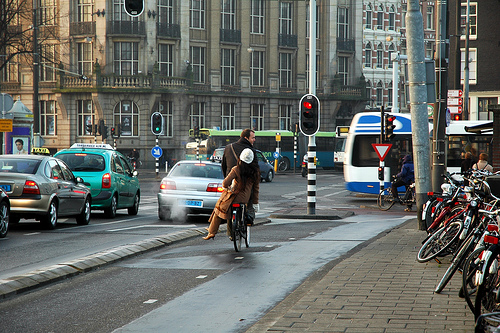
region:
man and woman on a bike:
[204, 127, 278, 253]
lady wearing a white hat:
[210, 148, 264, 236]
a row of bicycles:
[425, 161, 498, 331]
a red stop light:
[292, 92, 322, 139]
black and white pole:
[293, 67, 326, 221]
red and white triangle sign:
[371, 140, 391, 164]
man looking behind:
[223, 124, 263, 148]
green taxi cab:
[54, 139, 142, 216]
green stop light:
[148, 109, 165, 137]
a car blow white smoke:
[156, 154, 219, 213]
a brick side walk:
[334, 277, 406, 317]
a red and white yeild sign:
[371, 142, 393, 162]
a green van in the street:
[52, 146, 142, 214]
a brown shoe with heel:
[200, 233, 217, 240]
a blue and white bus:
[341, 112, 419, 207]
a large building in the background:
[1, 1, 363, 166]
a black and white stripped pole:
[305, 143, 322, 211]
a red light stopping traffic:
[301, 98, 313, 113]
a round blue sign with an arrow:
[151, 146, 163, 159]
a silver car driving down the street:
[157, 161, 234, 223]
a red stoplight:
[286, 89, 328, 141]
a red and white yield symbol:
[368, 138, 398, 159]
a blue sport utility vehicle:
[48, 141, 144, 217]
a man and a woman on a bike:
[201, 122, 273, 244]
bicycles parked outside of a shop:
[413, 147, 498, 332]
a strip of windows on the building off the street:
[60, 20, 327, 100]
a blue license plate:
[179, 197, 208, 209]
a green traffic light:
[143, 110, 168, 140]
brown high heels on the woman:
[202, 225, 218, 245]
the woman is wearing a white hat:
[237, 143, 253, 167]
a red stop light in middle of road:
[299, 87, 325, 141]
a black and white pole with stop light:
[298, 14, 323, 211]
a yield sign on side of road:
[373, 138, 391, 230]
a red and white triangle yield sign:
[373, 141, 390, 164]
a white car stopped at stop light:
[154, 152, 222, 211]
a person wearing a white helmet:
[239, 147, 254, 164]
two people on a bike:
[193, 122, 265, 264]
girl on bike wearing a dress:
[205, 185, 240, 257]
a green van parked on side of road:
[20, 143, 155, 208]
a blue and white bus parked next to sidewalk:
[342, 100, 419, 209]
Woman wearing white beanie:
[198, 144, 254, 242]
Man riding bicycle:
[201, 127, 260, 254]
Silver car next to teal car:
[154, 155, 225, 223]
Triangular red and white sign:
[368, 142, 393, 162]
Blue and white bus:
[339, 107, 499, 211]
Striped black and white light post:
[304, 140, 319, 215]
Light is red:
[298, 97, 314, 109]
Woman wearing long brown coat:
[200, 146, 260, 245]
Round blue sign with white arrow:
[150, 142, 165, 159]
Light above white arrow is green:
[152, 125, 163, 133]